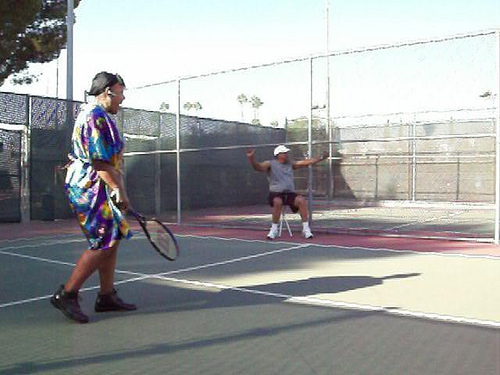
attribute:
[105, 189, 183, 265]
racket — tennis racket, in hand, large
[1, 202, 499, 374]
court — tennis court, red, green, existing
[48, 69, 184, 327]
player — tennis player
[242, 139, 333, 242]
spectator — at tennis match, sitting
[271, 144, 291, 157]
hat — white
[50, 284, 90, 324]
shoe — black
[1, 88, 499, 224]
fence — wire, chain link, privacy fence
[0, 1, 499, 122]
sky — blue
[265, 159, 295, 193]
tank top — gray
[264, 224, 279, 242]
shoe — white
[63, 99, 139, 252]
dress — printed, floral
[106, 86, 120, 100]
phone earpiece — bluetooth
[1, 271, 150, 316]
line — white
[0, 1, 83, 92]
tree — green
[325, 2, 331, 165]
pole — long